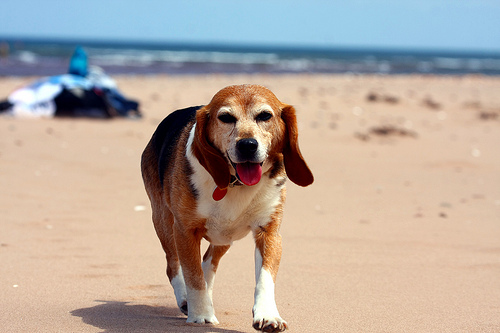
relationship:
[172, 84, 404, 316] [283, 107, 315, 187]
dog has ear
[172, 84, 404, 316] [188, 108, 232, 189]
dog has ear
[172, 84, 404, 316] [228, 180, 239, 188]
dog has collar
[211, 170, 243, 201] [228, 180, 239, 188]
tag on collar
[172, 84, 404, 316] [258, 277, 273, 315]
dog has fur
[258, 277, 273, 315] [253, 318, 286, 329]
fur by foot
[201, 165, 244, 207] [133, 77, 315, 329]
tag on neck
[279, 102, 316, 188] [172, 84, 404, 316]
ear belonging to dog